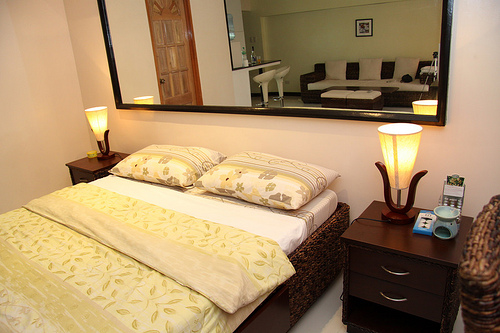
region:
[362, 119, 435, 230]
glowing lamp on nightstand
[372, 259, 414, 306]
handles on nightstand drawers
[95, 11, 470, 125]
mirror with wood frame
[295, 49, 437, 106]
reflection of couch in mirror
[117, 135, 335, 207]
two pillow on bed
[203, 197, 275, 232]
white sheet on bed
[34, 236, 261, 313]
turned down top of bedspread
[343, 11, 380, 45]
sqaure picture on wall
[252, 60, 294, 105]
two white modern chairs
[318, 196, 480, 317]
wood nightstand next to bed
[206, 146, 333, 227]
pillow on the bed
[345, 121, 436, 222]
lamp next to the bed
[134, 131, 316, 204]
two pillows on the bed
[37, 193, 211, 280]
blanket on the bed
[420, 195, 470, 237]
item on the table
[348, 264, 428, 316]
two drawers under the table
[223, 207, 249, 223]
white sheet on the bed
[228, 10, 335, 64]
mirror above the wall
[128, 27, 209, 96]
door in the mirror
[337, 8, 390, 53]
photo on the wall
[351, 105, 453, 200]
illuminated bedside lamp on cabinet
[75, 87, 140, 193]
illuminated bedside lamp on cabinet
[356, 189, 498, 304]
Brown wood cabinet with drawers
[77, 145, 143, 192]
Brown wood cabinet with drawers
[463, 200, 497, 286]
Brown wicker basket on right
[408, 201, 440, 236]
Blue remote control on cabinet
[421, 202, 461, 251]
Blue candle holder on cabinet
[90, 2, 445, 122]
Wide mirror above bed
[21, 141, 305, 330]
Full or queen size bed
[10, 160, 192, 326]
Lavish cream comforter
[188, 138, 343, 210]
pillow on a bed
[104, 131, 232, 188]
pillow on a bed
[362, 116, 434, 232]
wooden lamp with shade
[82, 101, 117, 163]
wooden lamp with shade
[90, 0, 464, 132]
mirror with wooden frame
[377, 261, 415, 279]
silver metal drawer pull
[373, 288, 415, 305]
silver metal drawer pull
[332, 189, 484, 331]
dark wooden night stand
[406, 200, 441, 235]
box of candles on the night stand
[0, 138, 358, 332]
bed with two pillows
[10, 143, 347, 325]
a nicely made double bed with a rattan frame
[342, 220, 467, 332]
a dark wood bedside table with two drawers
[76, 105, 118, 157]
a conical shaped small lamp on a small table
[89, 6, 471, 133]
a large mirror over the bed reflecting the opposite side of the room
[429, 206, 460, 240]
a light blue fragrance melting pot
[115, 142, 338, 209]
two fully pillows with a white and yellow design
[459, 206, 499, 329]
the edge of a rattan piece of furniture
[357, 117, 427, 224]
a conical shaped lamp with a wood base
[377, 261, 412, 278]
a silver handle on a drawer in the nightstand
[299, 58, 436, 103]
a large couch reflected in the mirror